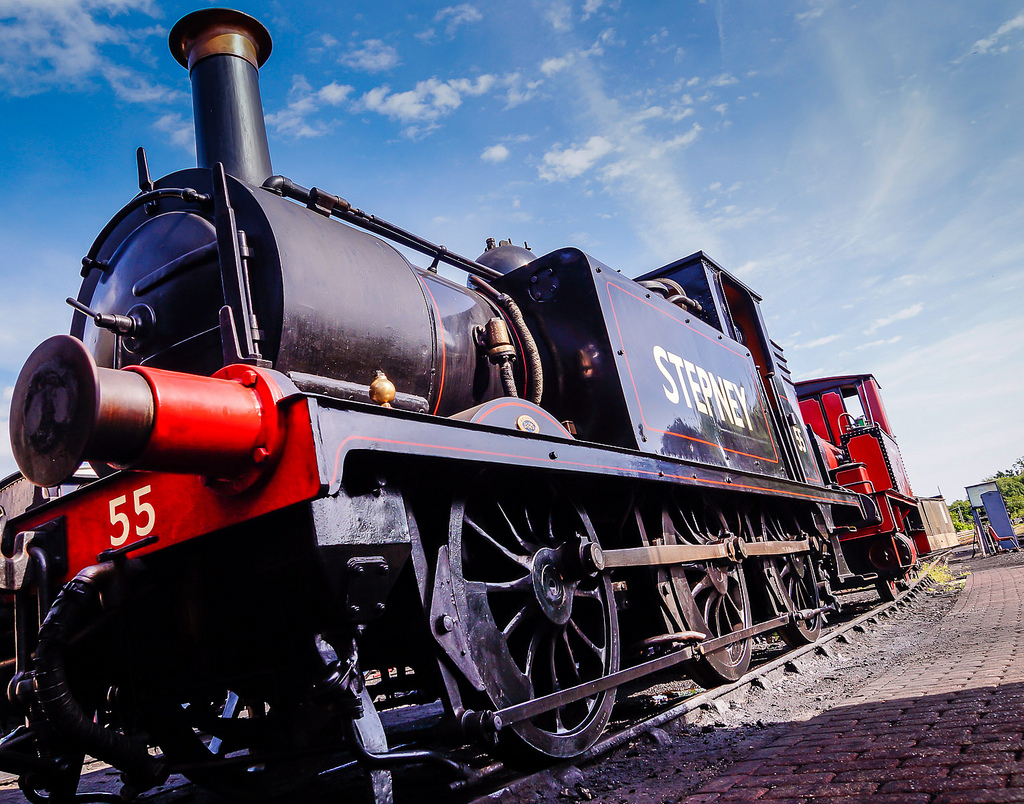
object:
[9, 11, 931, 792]
train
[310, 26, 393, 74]
cloud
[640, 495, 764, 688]
wheel